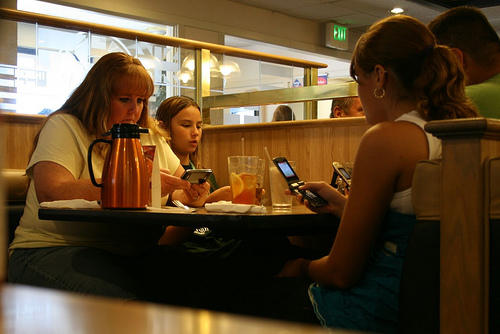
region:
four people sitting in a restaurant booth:
[3, 8, 499, 328]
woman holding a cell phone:
[275, 154, 325, 209]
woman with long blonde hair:
[23, 51, 171, 199]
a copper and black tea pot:
[86, 120, 152, 210]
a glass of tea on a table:
[230, 154, 258, 205]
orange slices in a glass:
[231, 170, 254, 198]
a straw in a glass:
[238, 138, 245, 160]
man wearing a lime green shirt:
[461, 70, 498, 119]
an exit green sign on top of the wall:
[326, 24, 350, 49]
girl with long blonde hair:
[157, 88, 214, 190]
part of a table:
[248, 224, 263, 241]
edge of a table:
[228, 230, 243, 242]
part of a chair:
[446, 258, 456, 281]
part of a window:
[31, 90, 55, 115]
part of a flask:
[111, 158, 136, 185]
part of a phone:
[280, 156, 287, 171]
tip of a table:
[227, 214, 232, 221]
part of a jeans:
[355, 303, 359, 310]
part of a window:
[232, 69, 238, 79]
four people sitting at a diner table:
[0, 13, 497, 258]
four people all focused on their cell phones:
[51, 19, 481, 248]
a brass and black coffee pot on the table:
[84, 122, 159, 212]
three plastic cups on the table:
[219, 145, 296, 207]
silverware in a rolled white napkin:
[198, 195, 266, 219]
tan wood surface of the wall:
[283, 127, 325, 158]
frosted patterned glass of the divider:
[27, 25, 184, 73]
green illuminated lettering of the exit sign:
[326, 18, 348, 46]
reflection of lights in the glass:
[162, 53, 238, 90]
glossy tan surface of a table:
[33, 291, 140, 331]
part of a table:
[458, 238, 475, 258]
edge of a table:
[207, 180, 223, 219]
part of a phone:
[291, 181, 298, 201]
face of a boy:
[188, 113, 203, 146]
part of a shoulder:
[381, 127, 395, 140]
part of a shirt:
[82, 160, 88, 166]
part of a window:
[249, 96, 256, 110]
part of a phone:
[288, 165, 298, 166]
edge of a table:
[438, 218, 448, 240]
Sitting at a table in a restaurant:
[43, 58, 460, 316]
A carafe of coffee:
[91, 121, 166, 231]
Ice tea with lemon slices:
[231, 146, 261, 216]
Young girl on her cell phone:
[308, 13, 457, 330]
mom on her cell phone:
[99, 73, 210, 213]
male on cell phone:
[435, 14, 499, 134]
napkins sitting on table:
[173, 198, 268, 214]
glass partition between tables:
[3, 19, 306, 114]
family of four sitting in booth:
[6, 111, 483, 332]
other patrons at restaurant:
[255, 86, 381, 120]